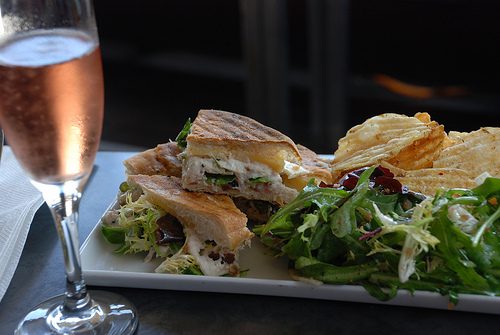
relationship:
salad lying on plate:
[258, 167, 498, 292] [60, 152, 498, 313]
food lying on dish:
[158, 130, 436, 249] [79, 176, 485, 313]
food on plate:
[180, 109, 311, 203] [78, 155, 499, 314]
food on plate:
[180, 109, 311, 203] [73, 146, 474, 318]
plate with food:
[89, 234, 499, 310] [129, 105, 498, 253]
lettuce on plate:
[250, 175, 492, 300] [66, 166, 496, 313]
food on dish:
[180, 109, 311, 203] [61, 182, 498, 314]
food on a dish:
[180, 109, 311, 203] [77, 192, 499, 317]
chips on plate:
[332, 111, 498, 190] [110, 260, 333, 295]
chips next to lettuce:
[332, 111, 498, 190] [266, 170, 498, 277]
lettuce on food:
[258, 166, 378, 238] [180, 109, 311, 203]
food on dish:
[180, 109, 311, 203] [55, 190, 482, 312]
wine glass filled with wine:
[1, 0, 139, 335] [0, 27, 105, 184]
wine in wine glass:
[2, 26, 108, 184] [0, 0, 138, 335]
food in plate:
[180, 109, 311, 203] [76, 197, 498, 314]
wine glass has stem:
[0, 0, 138, 335] [35, 184, 92, 310]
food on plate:
[180, 109, 311, 203] [79, 129, 496, 318]